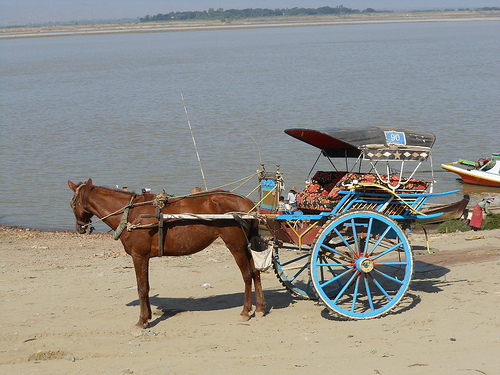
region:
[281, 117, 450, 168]
a black top on a buggy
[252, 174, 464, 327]
a blue buggy pulled behind a horse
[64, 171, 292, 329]
a brown horse pulling a buggy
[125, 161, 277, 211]
reins draped over a horse's back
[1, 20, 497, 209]
a body of water behind a horse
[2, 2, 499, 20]
a dark grey sky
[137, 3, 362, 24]
trees in the distance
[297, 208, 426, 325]
a large blue wheel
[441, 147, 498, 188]
a yellow and white boat on the water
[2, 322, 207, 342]
tracks in the sand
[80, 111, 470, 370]
a horse with carousel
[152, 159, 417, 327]
a horse with carousel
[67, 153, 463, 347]
horse and carriage on beach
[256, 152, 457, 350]
carriage has blue painted wheels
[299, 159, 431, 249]
red and black seat on carriage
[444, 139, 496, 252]
boat in water near beach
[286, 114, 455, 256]
black top on buggy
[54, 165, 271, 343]
horse standing on sand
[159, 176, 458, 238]
white and blue frame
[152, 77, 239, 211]
striped pole behind horse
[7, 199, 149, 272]
shells and rocks along beach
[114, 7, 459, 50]
shoreline in the distance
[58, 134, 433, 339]
Horse and buggy near water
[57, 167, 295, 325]
Horse standing on a beach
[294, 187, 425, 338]
Blue wagon wheel on buggy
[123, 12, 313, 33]
Trees and sand in far distance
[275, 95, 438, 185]
Roof of a two wheel buggy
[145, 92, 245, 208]
Buggy whip for a horse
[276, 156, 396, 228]
Bench of a two wheel buggy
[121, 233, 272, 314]
Legs of a hose standing on beach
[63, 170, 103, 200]
Ears of a brown horse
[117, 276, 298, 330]
Shadow of a horse on the beach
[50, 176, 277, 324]
a brown horse pulling a cart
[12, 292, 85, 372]
brown sandy road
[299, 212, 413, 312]
a large blue cart wheel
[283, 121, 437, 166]
a black cart cover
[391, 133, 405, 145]
the number 90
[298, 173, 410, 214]
a flower covered cart interior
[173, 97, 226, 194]
a red and white line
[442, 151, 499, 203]
the front end of a small boat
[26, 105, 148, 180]
muddy water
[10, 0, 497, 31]
land and trees in the distance